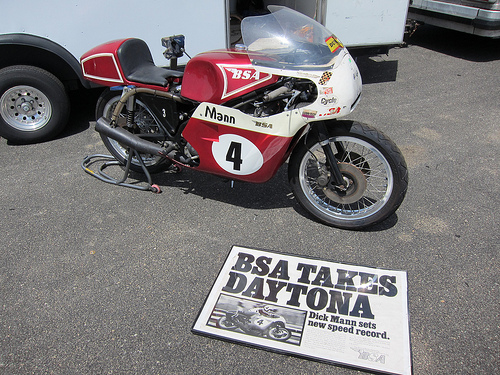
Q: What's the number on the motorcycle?
A: 4.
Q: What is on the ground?
A: The framed news headline page.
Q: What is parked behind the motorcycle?
A: The trailer.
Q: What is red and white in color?
A: The motorcycle.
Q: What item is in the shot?
A: The wheel.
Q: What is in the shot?
A: The poster.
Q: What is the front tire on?
A: The motorcycle.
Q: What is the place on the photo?
A: Daytona.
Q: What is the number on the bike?
A: 4.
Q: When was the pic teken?
A: During the day.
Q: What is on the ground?
A: News paper.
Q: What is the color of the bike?
A: Red.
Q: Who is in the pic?
A: No one.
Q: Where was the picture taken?
A: In a parking lot.